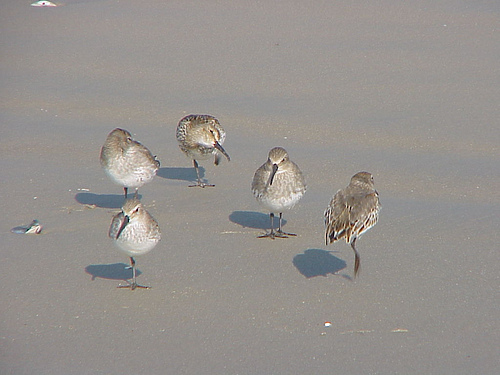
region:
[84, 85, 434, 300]
birds standing on the ground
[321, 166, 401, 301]
bird taking off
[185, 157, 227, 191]
one one foot on the ground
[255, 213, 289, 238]
both feet on the ground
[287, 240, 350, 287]
shadow on the ground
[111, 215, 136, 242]
long gray beak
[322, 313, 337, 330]
bit of white on the ground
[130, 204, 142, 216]
small black eye on the side of the head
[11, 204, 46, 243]
feather on the ground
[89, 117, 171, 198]
bird with its head bent around its body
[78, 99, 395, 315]
five sandpipers, all doing different things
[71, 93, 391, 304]
i think these are all rock, least, or maybe spotted sandpipers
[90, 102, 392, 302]
whichever they are [they all look really similar], they are out of breeding season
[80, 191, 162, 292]
sandpiper 1 [furthest left] has cynical expression, one leg behind the other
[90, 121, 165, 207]
sp2 is either pretending or trying to sleep, head under wing, in the daytime amid a gang of sandpipers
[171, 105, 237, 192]
sp3 [middle] has an itchy head, is using leg to scratch it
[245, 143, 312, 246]
sp4 [second right] looks slightly crabby, is standing firmly upright on both feet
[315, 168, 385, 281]
sp5 [right] is turned away from us to hop on one leg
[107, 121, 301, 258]
viewer can really see only 3 sandpiper's expressions. of these, two are cranky.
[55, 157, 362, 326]
five sandpiper shadows, first left is best silhouette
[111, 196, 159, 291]
A grey bird standing on one leg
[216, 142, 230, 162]
A black beak of a bird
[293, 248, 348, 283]
A shadow of a bird on the ground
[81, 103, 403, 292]
Group of birds of the same family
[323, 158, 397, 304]
a bird attempting to fly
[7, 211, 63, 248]
A bird hidding under the sand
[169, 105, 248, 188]
A bird scraching it's ear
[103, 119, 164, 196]
A bird sleeping while standing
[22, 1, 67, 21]
A white stone on the ground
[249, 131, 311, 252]
a bird standing on the ground with both feet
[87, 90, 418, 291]
A group of birds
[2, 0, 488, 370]
A sandy landscape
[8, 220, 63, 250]
A feather in the sand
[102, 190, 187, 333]
A grey and white bird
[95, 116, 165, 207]
A grey and white bird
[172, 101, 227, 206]
A grey and white bird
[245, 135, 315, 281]
A grey and white bird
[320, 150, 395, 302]
A grey and white bird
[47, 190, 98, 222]
animal tracks in the sand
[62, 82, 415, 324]
some birds standing on a beach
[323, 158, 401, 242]
this is a bird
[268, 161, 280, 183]
this is the beak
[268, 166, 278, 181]
thje3 beak is black in color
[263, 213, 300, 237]
this is the leg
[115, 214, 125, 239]
the beak is long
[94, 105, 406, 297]
the birds are five in number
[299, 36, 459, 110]
this is a water body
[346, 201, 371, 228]
this is the wing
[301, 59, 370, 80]
the water is cool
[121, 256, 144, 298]
the bird is standing on one leg